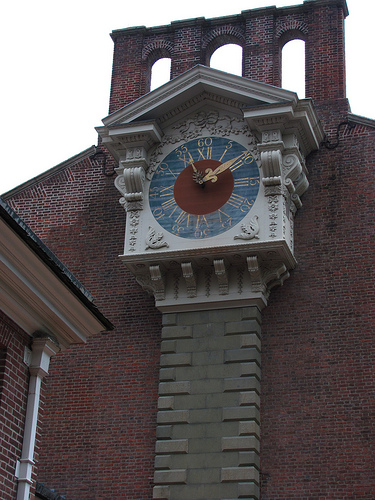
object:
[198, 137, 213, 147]
60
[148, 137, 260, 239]
clock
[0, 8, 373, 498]
building